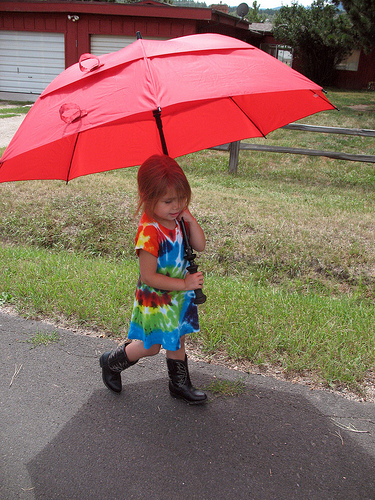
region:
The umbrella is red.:
[0, 29, 342, 181]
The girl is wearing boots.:
[105, 152, 212, 418]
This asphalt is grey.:
[29, 383, 89, 472]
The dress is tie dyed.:
[124, 213, 208, 348]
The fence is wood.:
[227, 130, 372, 171]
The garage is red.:
[0, 8, 272, 108]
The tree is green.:
[273, 6, 367, 86]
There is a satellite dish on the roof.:
[235, 3, 251, 19]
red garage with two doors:
[0, 2, 249, 96]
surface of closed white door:
[1, 31, 64, 93]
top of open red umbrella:
[0, 32, 335, 183]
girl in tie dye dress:
[90, 153, 206, 401]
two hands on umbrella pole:
[172, 212, 205, 303]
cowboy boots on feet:
[98, 340, 204, 400]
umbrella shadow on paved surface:
[27, 369, 370, 495]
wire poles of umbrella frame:
[58, 91, 334, 175]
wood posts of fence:
[221, 122, 373, 171]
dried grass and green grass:
[4, 96, 372, 392]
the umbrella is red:
[0, 31, 324, 179]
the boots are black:
[93, 333, 207, 404]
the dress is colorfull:
[120, 221, 210, 346]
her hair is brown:
[135, 153, 197, 204]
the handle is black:
[187, 262, 207, 313]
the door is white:
[7, 30, 60, 94]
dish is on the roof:
[233, 2, 249, 21]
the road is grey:
[15, 408, 366, 497]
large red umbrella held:
[0, 17, 325, 171]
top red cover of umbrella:
[56, 30, 197, 90]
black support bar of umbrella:
[63, 138, 87, 174]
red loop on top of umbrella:
[52, 102, 82, 132]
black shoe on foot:
[162, 354, 212, 409]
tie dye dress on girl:
[112, 217, 202, 360]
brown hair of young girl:
[120, 160, 196, 226]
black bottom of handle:
[187, 256, 204, 306]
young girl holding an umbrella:
[1, 6, 340, 348]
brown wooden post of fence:
[245, 142, 368, 165]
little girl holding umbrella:
[0, 17, 338, 406]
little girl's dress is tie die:
[126, 211, 203, 354]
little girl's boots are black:
[96, 338, 209, 407]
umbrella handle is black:
[153, 108, 210, 307]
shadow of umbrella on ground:
[16, 364, 372, 494]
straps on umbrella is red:
[53, 49, 101, 122]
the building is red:
[1, 1, 272, 106]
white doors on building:
[1, 27, 172, 102]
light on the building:
[64, 11, 85, 27]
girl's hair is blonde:
[134, 154, 194, 220]